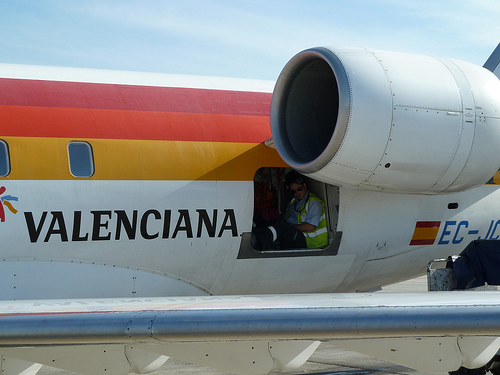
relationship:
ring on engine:
[270, 46, 348, 171] [262, 40, 498, 192]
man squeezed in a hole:
[259, 182, 333, 252] [253, 167, 334, 261]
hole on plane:
[253, 167, 334, 261] [4, 29, 498, 372]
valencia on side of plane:
[19, 204, 240, 247] [4, 29, 498, 372]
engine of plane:
[262, 40, 498, 192] [4, 29, 498, 372]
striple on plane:
[0, 136, 273, 187] [4, 29, 498, 372]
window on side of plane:
[64, 134, 100, 188] [4, 29, 498, 372]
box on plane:
[404, 213, 445, 247] [4, 29, 498, 372]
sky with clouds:
[4, 2, 498, 82] [4, 2, 496, 89]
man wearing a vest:
[259, 182, 333, 252] [288, 194, 342, 250]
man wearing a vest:
[259, 182, 333, 252] [292, 204, 326, 256]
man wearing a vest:
[259, 182, 333, 252] [286, 198, 329, 252]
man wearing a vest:
[259, 182, 333, 252] [288, 198, 333, 250]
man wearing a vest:
[259, 182, 333, 252] [281, 189, 328, 245]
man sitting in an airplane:
[259, 182, 333, 252] [2, 47, 487, 372]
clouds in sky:
[1, 2, 497, 69] [4, 2, 498, 82]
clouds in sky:
[1, 2, 497, 69] [2, 0, 498, 69]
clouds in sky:
[1, 4, 499, 78] [4, 2, 498, 82]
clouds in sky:
[4, 2, 496, 89] [2, 2, 498, 94]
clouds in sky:
[4, 2, 496, 89] [4, 2, 498, 82]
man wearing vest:
[259, 182, 333, 252] [279, 198, 333, 248]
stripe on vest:
[301, 225, 326, 243] [286, 193, 333, 254]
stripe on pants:
[266, 222, 282, 247] [250, 218, 302, 248]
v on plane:
[19, 205, 48, 246] [4, 29, 498, 372]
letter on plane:
[48, 207, 71, 251] [16, 44, 476, 349]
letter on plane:
[160, 198, 170, 238] [0, 57, 483, 325]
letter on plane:
[87, 196, 110, 256] [15, 31, 439, 371]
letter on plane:
[155, 196, 177, 253] [16, 44, 476, 349]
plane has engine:
[4, 29, 498, 372] [257, 42, 498, 209]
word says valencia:
[22, 202, 238, 251] [19, 204, 240, 247]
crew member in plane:
[279, 180, 329, 240] [4, 29, 498, 372]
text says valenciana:
[19, 205, 242, 252] [19, 205, 240, 248]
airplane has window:
[2, 47, 487, 372] [62, 134, 103, 177]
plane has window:
[4, 29, 498, 372] [61, 133, 99, 180]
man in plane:
[259, 182, 333, 252] [4, 29, 498, 372]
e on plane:
[428, 207, 460, 262] [45, 20, 450, 340]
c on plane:
[450, 208, 469, 250] [16, 44, 476, 349]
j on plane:
[469, 218, 497, 253] [50, 41, 475, 334]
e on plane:
[443, 210, 466, 253] [48, 58, 444, 336]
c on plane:
[137, 200, 165, 243] [15, 24, 466, 335]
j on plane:
[483, 208, 487, 234] [47, 41, 457, 371]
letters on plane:
[15, 183, 251, 267] [28, 43, 497, 291]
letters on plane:
[434, 205, 476, 264] [7, 33, 401, 368]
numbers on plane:
[480, 210, 490, 240] [7, 33, 401, 368]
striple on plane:
[23, 47, 278, 197] [48, 58, 444, 336]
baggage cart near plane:
[433, 232, 487, 302] [6, 39, 463, 362]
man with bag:
[259, 182, 333, 252] [293, 207, 360, 257]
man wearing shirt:
[259, 182, 333, 252] [265, 183, 330, 225]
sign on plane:
[31, 166, 223, 264] [28, 43, 497, 291]